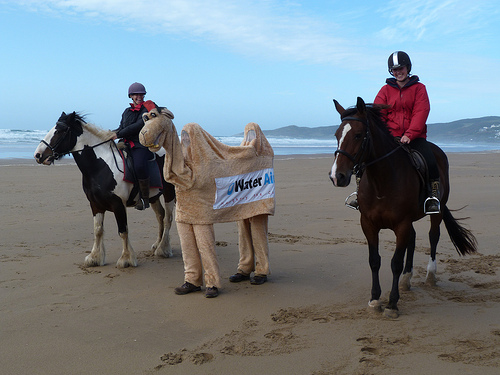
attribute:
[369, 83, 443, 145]
jacket — red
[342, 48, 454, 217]
person — riding, laughing, sitting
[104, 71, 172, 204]
person — riding, sitting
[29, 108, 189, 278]
horse — paint, brown, white, beautiful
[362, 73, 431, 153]
jacket — red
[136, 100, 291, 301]
people — disguised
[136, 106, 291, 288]
costume — tan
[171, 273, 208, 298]
shoe — dark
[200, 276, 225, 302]
shoe — dark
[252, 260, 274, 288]
shoe — dark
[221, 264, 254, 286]
shoe — dark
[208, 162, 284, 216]
advertisement — white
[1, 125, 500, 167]
water — blue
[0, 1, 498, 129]
sky — blue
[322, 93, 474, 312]
horse — brown, white, beautiful, dark brown